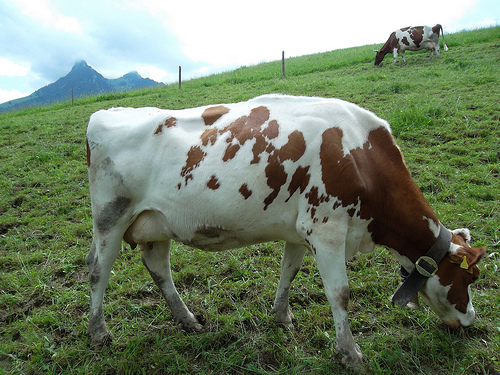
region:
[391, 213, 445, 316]
Collar the cow is wearing.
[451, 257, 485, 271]
Tag in the cow's ear.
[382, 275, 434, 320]
Cow bell on the cow's collar.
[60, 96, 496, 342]
White and brown cow grazing.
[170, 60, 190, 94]
Fence post keeping the cows in.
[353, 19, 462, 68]
Other brown and white cow.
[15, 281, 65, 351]
Green grass in the field.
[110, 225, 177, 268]
Udders of the cow.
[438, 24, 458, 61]
Tail of the cow.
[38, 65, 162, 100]
Mountains in the background.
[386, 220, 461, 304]
the cow has a grey collar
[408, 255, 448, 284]
the collar has a silver metal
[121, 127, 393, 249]
the cow has brown and white spots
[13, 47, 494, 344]
the ground is sloopy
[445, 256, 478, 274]
the ear has a yellow tag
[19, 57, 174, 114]
the mountain is furthest away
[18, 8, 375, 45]
the sky is cloudy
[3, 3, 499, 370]
there are two cows in the picture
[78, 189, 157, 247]
there is grey dirt on the leg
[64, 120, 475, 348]
the cow has four legs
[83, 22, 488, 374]
two cows are grazing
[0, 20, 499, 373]
green grass on hillside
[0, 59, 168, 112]
mountains in the background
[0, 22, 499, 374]
hillside is very steep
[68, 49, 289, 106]
fence posts behind cows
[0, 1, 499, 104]
sky is cloudy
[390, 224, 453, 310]
cow has black leather collar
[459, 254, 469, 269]
cow has yellow ear tag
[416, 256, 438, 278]
collar has metal belt closure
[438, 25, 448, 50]
cow has tail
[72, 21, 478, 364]
two cows grazing in a grassy pasture.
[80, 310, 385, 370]
a cow's hoofs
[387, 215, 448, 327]
a cow's collar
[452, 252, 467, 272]
a cow's ear tag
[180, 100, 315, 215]
brown spots on a cow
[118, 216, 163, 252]
a cow's udders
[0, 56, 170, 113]
a mountain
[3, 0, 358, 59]
a cloudy sky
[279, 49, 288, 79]
a fence post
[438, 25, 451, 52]
the tail of a cow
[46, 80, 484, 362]
Brown and white cow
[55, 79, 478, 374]
Brown and white cow with collar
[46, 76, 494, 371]
Cow wearing a leather collar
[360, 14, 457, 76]
medium sized brown and white cow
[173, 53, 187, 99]
Large wooden fence post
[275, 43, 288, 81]
Large wooden fence post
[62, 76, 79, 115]
Large wooden fence post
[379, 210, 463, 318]
Leather collar with metal buckle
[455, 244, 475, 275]
Yellow plastic livestock tag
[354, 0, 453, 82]
Cow eating grass